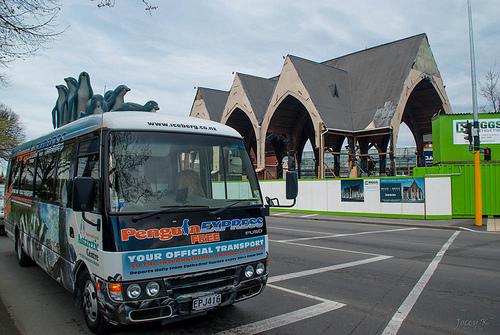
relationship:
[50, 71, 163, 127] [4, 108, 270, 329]
penguins on bus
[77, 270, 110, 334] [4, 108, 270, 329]
tire on bus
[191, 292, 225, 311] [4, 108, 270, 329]
license plate on bus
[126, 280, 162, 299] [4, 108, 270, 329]
headlights on bus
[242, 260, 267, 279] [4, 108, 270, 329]
headlights on bus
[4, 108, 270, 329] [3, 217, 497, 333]
bus on road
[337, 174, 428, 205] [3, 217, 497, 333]
sign by road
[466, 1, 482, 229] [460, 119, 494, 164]
pole for traffic light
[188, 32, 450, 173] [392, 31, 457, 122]
building has steeple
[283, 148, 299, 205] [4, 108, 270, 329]
mirror on bus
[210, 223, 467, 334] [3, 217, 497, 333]
lines on road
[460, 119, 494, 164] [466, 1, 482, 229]
traffic light on pole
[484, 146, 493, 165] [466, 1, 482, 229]
crossing signal on pole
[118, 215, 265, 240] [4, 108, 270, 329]
penguin express on bus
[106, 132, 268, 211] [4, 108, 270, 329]
windshield on bus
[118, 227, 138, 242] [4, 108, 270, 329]
letters on bus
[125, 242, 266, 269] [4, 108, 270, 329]
red letters on bus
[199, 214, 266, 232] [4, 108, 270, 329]
blue letters on bus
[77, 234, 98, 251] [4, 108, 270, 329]
letters on bus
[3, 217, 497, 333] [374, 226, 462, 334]
road has lines